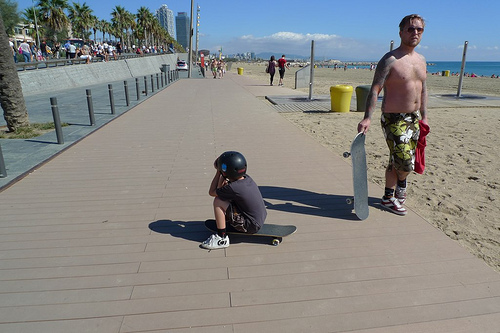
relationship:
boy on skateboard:
[198, 151, 266, 250] [222, 223, 297, 244]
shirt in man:
[410, 117, 430, 174] [358, 12, 430, 217]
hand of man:
[419, 118, 427, 126] [358, 12, 430, 217]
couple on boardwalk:
[266, 57, 287, 86] [7, 57, 497, 331]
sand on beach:
[428, 102, 498, 222] [342, 57, 495, 77]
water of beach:
[467, 57, 493, 74] [228, 61, 498, 267]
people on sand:
[428, 68, 499, 80] [246, 62, 498, 271]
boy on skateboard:
[198, 151, 266, 250] [203, 217, 294, 248]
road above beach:
[22, 63, 151, 75] [446, 140, 480, 222]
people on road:
[61, 44, 128, 53] [22, 63, 151, 75]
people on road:
[17, 39, 61, 53] [22, 63, 151, 75]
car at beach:
[176, 60, 187, 70] [228, 61, 498, 267]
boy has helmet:
[198, 151, 266, 249] [214, 150, 248, 181]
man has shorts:
[382, 34, 426, 199] [379, 110, 426, 172]